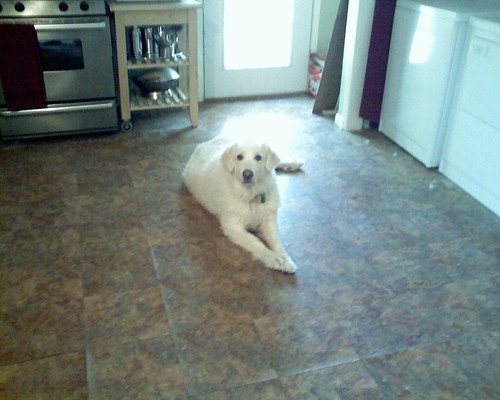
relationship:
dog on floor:
[180, 128, 305, 274] [1, 95, 485, 397]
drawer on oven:
[0, 97, 120, 142] [0, 0, 121, 140]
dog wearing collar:
[180, 128, 305, 274] [246, 195, 265, 205]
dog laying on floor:
[180, 128, 305, 274] [1, 95, 485, 397]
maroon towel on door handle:
[0, 25, 47, 112] [13, 18, 106, 24]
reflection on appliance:
[399, 0, 441, 74] [378, 0, 495, 171]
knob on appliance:
[80, 2, 93, 14] [2, 0, 119, 139]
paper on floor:
[426, 176, 456, 190] [0, 1, 499, 398]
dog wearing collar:
[180, 128, 305, 274] [257, 193, 264, 203]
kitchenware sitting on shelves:
[158, 38, 175, 57] [139, 65, 189, 68]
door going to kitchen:
[205, 0, 312, 97] [0, 2, 498, 399]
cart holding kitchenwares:
[108, 18, 189, 130] [123, 21, 190, 111]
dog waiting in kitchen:
[180, 128, 305, 274] [0, 2, 498, 399]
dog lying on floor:
[180, 128, 305, 274] [1, 95, 485, 397]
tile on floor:
[0, 87, 498, 398] [1, 95, 485, 397]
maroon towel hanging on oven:
[0, 25, 49, 115] [0, 0, 121, 140]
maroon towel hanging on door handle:
[0, 25, 49, 115] [12, 15, 107, 32]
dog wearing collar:
[162, 122, 332, 274] [257, 193, 264, 203]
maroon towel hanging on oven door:
[0, 25, 47, 112] [3, 15, 117, 101]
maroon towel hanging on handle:
[0, 25, 47, 112] [10, 13, 112, 35]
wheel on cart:
[100, 100, 164, 153] [92, 6, 234, 131]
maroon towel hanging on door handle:
[0, 25, 47, 112] [13, 18, 106, 24]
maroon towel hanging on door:
[0, 25, 47, 112] [1, 15, 111, 104]